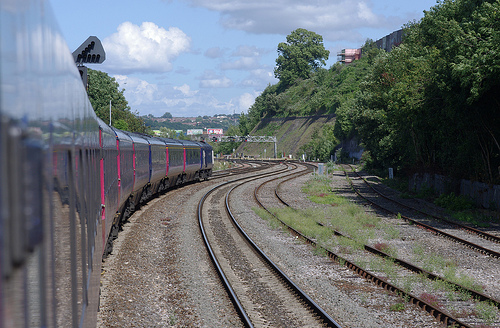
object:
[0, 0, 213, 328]
train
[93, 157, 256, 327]
track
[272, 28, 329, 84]
tree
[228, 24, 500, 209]
hillside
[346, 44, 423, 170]
tree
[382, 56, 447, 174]
tree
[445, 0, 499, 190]
tree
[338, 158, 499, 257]
track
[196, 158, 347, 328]
track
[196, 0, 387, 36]
cloud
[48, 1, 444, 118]
sky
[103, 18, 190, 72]
cloud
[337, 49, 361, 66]
building